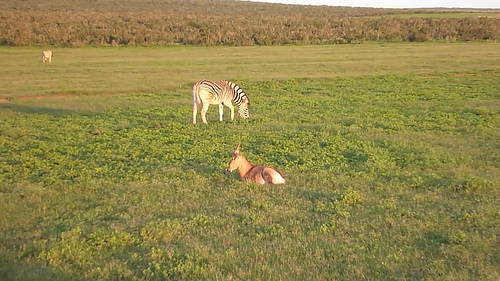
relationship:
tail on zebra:
[192, 86, 201, 103] [188, 82, 250, 127]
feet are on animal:
[191, 118, 207, 125] [192, 79, 250, 125]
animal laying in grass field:
[226, 142, 286, 185] [20, 72, 483, 271]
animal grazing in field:
[192, 79, 250, 125] [6, 69, 476, 259]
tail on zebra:
[195, 86, 202, 106] [190, 77, 253, 130]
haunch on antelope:
[256, 162, 285, 183] [226, 142, 290, 187]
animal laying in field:
[226, 142, 286, 185] [0, 0, 499, 278]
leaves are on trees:
[373, 10, 418, 40] [433, 14, 467, 44]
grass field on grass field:
[0, 41, 500, 278] [0, 41, 500, 278]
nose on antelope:
[226, 159, 238, 175] [207, 133, 294, 188]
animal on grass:
[41, 47, 53, 62] [0, 41, 499, 279]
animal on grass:
[192, 79, 250, 125] [0, 41, 499, 279]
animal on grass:
[226, 140, 287, 186] [0, 41, 499, 279]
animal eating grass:
[192, 79, 250, 125] [0, 41, 499, 279]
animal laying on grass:
[182, 76, 253, 127] [58, 174, 457, 263]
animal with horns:
[226, 140, 287, 186] [229, 138, 243, 154]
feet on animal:
[216, 103, 235, 121] [192, 79, 250, 125]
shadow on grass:
[3, 100, 113, 118] [0, 41, 499, 279]